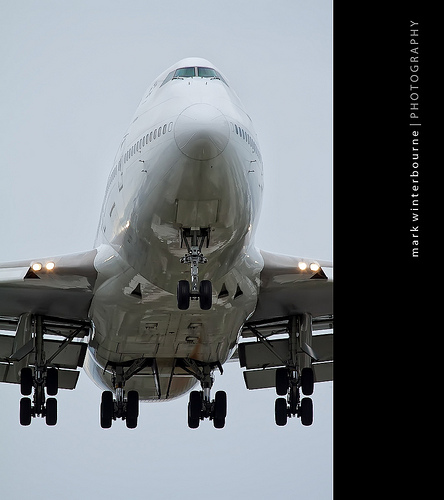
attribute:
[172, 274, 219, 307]
wheels — plane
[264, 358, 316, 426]
wheels — plane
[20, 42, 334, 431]
plane — one